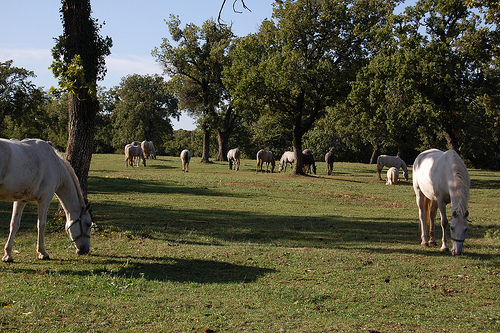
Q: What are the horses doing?
A: Eating.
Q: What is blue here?
A: The sky.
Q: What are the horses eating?
A: Grass.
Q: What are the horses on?
A: Grass.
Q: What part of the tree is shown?
A: The trunk.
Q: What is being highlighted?
A: Trees with green leaves.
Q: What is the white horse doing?
A: Grazing.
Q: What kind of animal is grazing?
A: A horse.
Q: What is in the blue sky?
A: Puffy clouds.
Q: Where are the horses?
A: In a field of grass.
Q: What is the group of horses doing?
A: Grazing.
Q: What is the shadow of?
A: A standing horse.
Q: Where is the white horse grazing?
A: In a field.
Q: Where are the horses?
A: On the field.